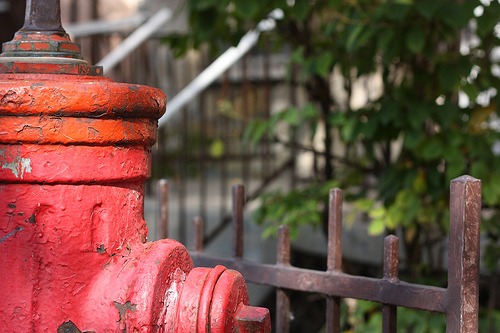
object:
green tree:
[160, 0, 500, 280]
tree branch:
[234, 113, 375, 187]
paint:
[0, 89, 23, 122]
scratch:
[0, 144, 33, 179]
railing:
[95, 0, 183, 77]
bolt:
[230, 305, 272, 332]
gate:
[231, 174, 499, 332]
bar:
[327, 186, 343, 271]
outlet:
[116, 238, 273, 332]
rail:
[159, 0, 297, 135]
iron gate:
[276, 174, 481, 332]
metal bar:
[381, 233, 399, 278]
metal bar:
[276, 223, 290, 267]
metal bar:
[231, 182, 244, 255]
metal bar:
[192, 216, 202, 251]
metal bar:
[155, 177, 168, 238]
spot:
[0, 26, 105, 77]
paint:
[105, 295, 139, 322]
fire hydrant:
[0, 0, 273, 332]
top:
[0, 0, 81, 56]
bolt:
[19, 0, 67, 33]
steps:
[137, 162, 330, 307]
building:
[53, 0, 499, 306]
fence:
[157, 174, 482, 332]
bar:
[447, 174, 482, 332]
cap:
[209, 268, 272, 332]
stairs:
[90, 0, 315, 251]